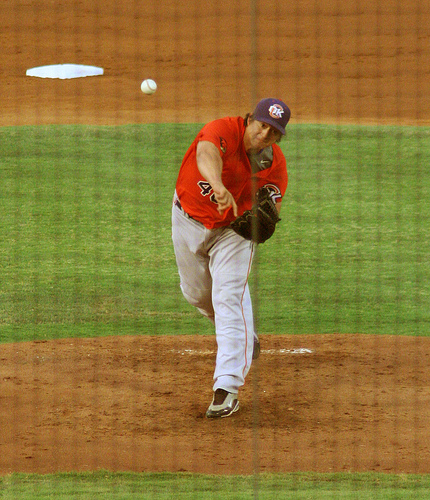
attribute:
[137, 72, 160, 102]
baseball — flying, white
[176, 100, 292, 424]
player — baseball player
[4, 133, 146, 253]
grass on field — green, well-manicured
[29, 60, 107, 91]
plate on field — white, square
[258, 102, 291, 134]
blue cap — dark blue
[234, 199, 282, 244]
mitt — black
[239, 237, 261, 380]
red stripe — pinstripe